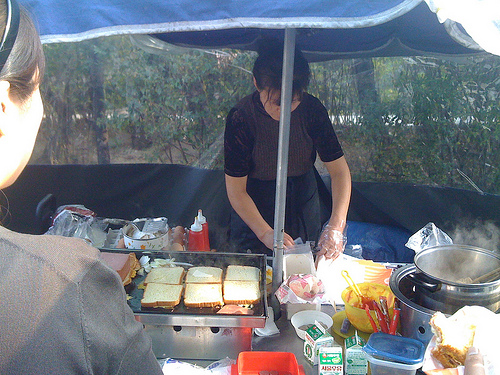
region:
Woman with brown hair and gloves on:
[218, 42, 352, 262]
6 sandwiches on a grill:
[138, 257, 265, 312]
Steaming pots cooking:
[381, 233, 498, 343]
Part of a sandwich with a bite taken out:
[431, 307, 487, 374]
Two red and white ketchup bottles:
[187, 209, 211, 250]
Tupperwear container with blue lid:
[361, 332, 426, 373]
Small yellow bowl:
[341, 284, 396, 328]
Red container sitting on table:
[235, 349, 306, 374]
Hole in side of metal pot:
[417, 324, 424, 334]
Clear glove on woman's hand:
[315, 220, 348, 260]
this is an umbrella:
[223, 39, 347, 261]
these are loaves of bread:
[142, 265, 258, 307]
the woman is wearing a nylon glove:
[315, 224, 348, 265]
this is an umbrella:
[9, 3, 494, 37]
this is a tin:
[366, 332, 426, 373]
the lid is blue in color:
[364, 332, 424, 365]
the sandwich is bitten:
[431, 307, 464, 363]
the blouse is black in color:
[233, 102, 267, 173]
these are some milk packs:
[307, 327, 339, 364]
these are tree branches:
[396, 57, 483, 188]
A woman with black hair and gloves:
[221, 46, 355, 258]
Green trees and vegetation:
[363, 75, 497, 127]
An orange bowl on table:
[237, 347, 302, 373]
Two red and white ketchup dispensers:
[188, 209, 213, 253]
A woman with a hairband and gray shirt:
[1, 1, 158, 373]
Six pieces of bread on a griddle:
[140, 261, 260, 311]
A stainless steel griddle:
[159, 310, 265, 363]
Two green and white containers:
[305, 320, 343, 372]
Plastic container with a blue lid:
[371, 335, 424, 372]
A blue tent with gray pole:
[62, 2, 399, 50]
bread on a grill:
[144, 261, 265, 313]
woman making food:
[281, 222, 359, 314]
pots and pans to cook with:
[393, 236, 495, 360]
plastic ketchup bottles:
[181, 205, 228, 261]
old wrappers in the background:
[43, 198, 136, 250]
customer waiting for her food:
[6, 15, 80, 240]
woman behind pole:
[220, 48, 364, 218]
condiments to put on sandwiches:
[333, 266, 398, 351]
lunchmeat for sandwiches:
[96, 241, 143, 288]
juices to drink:
[300, 323, 369, 373]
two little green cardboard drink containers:
[317, 326, 370, 373]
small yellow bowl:
[342, 281, 395, 328]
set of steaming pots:
[389, 239, 499, 339]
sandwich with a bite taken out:
[425, 302, 482, 364]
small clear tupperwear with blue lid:
[362, 329, 426, 374]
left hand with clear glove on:
[317, 229, 347, 266]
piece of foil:
[42, 210, 128, 247]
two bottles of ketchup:
[185, 209, 212, 250]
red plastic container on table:
[230, 348, 307, 374]